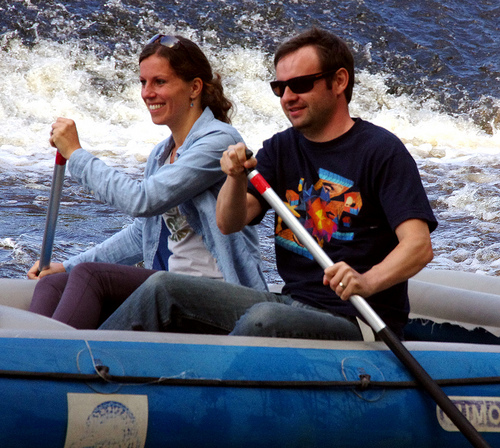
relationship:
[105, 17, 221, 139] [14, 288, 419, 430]
woman on boat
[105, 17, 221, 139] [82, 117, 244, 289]
woman wearing blazer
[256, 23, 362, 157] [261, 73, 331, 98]
man wearing sunglasses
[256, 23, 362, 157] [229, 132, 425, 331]
man wearing tshirt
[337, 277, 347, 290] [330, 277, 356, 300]
ring on finger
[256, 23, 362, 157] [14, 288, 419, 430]
man on boat